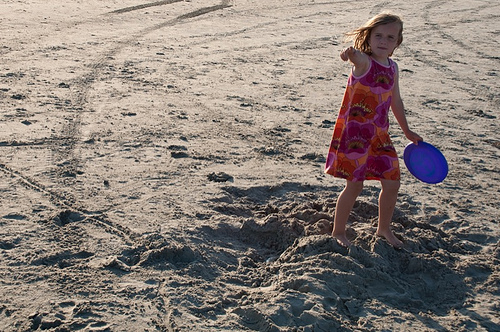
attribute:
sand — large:
[84, 75, 251, 187]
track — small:
[8, 132, 180, 264]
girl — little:
[329, 12, 425, 255]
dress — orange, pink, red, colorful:
[322, 50, 401, 182]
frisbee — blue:
[400, 139, 450, 184]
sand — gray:
[250, 187, 462, 318]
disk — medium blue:
[396, 130, 453, 200]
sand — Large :
[36, 33, 286, 210]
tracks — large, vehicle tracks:
[7, 0, 238, 323]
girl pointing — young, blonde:
[320, 10, 430, 250]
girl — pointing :
[332, 10, 412, 255]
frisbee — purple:
[403, 142, 448, 184]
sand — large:
[2, 1, 498, 329]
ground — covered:
[4, 8, 498, 326]